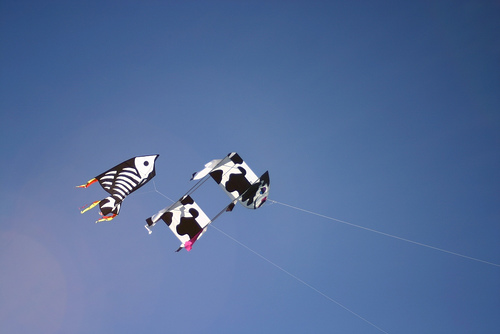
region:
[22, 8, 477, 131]
the sky is blue and clear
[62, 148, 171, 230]
the kite in the sky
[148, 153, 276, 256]
the kite in the sky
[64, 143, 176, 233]
the kite is flying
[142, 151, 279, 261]
the kite is flying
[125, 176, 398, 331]
the string on the kite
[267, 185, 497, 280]
the string on the kite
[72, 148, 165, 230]
the kite is a fish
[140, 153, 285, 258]
the kite is a cow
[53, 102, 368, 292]
kites in the sky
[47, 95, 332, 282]
two kites in the air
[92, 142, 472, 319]
two line are controlling two lines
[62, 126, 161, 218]
a fish kite in the sky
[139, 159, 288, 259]
this kite resembles a cow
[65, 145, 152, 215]
the fish kite has a red and yellow ribbons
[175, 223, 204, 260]
a pink ribbon on the cow designed kite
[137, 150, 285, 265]
this kite has a rectangle shape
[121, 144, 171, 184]
the head of the fish kite it white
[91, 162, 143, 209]
the body of the fish kite has black and white stripes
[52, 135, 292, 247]
these kites are flying next to each other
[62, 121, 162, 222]
this is a kite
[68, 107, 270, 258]
two kites in the sky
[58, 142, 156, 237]
kite shaped like a fish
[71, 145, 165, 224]
black trim on fish kite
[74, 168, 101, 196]
red tail on kite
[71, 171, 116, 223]
tail sticking off of kite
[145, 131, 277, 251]
kite shaped like a cow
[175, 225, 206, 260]
pink tail on kite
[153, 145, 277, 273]
cow kite is black and white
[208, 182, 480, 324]
white strings connected to kites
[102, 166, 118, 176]
The line is white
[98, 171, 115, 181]
The line is white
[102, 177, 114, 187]
The line is white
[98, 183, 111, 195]
The line is white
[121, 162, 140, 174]
The line is white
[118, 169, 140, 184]
The line is white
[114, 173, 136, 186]
The line is white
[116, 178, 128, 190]
The line is white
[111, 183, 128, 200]
The line is white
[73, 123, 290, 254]
Black in white kite in the sky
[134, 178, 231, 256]
Black in white kite in the sky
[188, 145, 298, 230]
Black in white kite in the sky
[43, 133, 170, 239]
Black in white kite in the sky